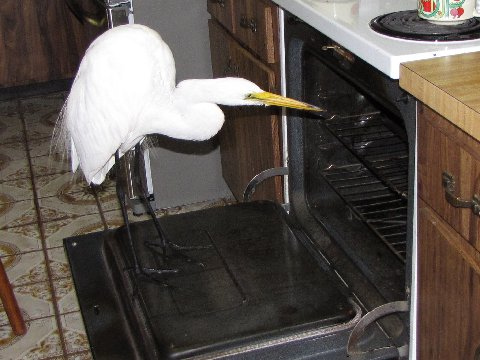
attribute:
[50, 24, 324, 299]
bird — white, looking, standing, big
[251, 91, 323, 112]
beak — yellow, orange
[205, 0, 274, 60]
drawer — wooden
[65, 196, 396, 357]
oven door — open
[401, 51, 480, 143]
countertop — brown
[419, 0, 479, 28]
container — ceramic, white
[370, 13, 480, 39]
burner — round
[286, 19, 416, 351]
oven — black, open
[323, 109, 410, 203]
rack — metal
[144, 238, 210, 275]
foot — black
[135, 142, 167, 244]
leg — black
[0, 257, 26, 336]
stool — brown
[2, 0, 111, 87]
paneling — brown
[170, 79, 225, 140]
neck — curved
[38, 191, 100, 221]
tile — brown, old